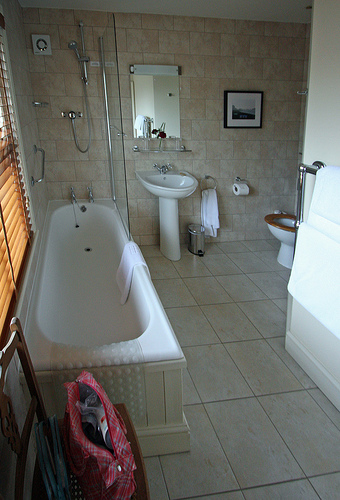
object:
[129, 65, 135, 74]
light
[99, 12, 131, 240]
partition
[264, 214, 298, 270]
toilet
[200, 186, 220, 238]
towel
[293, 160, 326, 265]
rack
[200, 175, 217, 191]
rack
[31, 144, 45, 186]
rack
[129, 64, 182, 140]
bathroom mirror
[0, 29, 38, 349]
blinds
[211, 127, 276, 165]
wall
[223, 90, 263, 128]
picture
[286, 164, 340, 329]
towels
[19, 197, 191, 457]
bath tub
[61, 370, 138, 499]
bag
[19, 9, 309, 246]
wall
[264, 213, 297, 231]
seat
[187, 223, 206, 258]
trash can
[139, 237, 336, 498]
floor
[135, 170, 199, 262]
sink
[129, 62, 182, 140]
mirror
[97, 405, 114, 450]
tube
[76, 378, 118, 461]
zipper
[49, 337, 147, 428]
mat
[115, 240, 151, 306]
towel